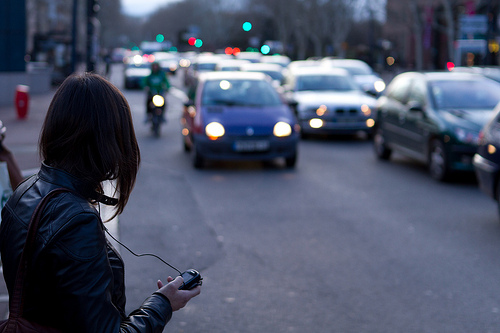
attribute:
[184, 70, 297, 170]
vehicle — blurry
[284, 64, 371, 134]
vehicle — blurry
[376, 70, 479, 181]
vehicle — blurry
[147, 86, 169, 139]
vehicle — blurry